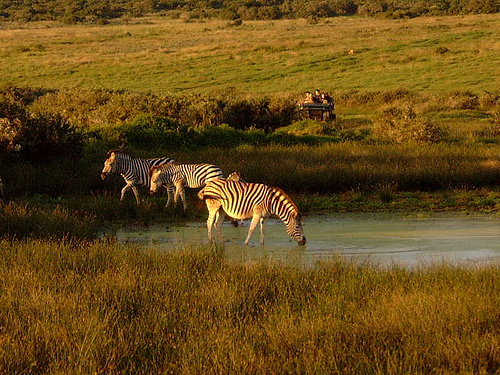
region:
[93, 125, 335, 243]
Zebra's in a pasture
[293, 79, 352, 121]
People watching the zebras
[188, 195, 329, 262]
Zebra drinking out of body of water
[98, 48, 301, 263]
Black and white stripes on zebras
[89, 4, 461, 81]
Brown and green grass in field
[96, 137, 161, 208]
Zebra walking in the grass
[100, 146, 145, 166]
Black hair on top of zebra's head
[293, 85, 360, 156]
People sitting watching zebras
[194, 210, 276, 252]
4 legs on zebra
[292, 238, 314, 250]
Black nose on zebra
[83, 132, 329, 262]
A group of zebras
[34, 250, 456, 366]
Tall yellow and green grass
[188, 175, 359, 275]
A zebra drink from water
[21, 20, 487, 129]
A hillside cover in grass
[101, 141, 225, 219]
A pair of zebras walking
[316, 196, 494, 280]
A small pond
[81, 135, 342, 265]
Zebras in their natural habitat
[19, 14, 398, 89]
Dead grass on the hill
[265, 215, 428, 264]
Ripples in water due to zebra drinking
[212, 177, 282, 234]
Stripes on a zebra's body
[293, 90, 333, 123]
a group of tourists on a safari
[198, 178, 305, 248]
a zebra drinking water from a watering hole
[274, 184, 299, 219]
a zebra has a brown mane along the back of its neck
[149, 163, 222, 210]
a zebra has vertical and horizontal black stripes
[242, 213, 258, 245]
the zebras front legs do not have any stripes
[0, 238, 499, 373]
tall grazing grass for the zebras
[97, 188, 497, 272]
a small watering hole in the plains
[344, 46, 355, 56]
a lion in the distance is watching the activity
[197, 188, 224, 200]
the zebra's tail has long black hairs at the tip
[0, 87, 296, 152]
thick vegetation surounds the watering hole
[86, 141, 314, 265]
Zebras in a creek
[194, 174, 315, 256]
Zebra drinking water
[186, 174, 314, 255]
Zebra has tail on right side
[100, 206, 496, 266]
Creek in the meadow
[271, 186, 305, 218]
Mane has brown borders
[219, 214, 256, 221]
Underbelly of zebra is white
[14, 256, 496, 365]
Grass is high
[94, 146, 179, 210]
Zebra walking in the bank of creek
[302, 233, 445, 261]
Ripples formed in the water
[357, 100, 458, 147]
Bush on the field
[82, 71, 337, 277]
zebras at pool of water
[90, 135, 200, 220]
two zebras headed the same way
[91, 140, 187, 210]
a pair of zebras walking together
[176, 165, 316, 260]
zebra drinking water from pond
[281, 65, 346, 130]
boxy structure above pond with objects on top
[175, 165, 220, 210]
tail curved around body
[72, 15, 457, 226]
sloped grassland above pond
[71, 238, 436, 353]
tall and thin vegetation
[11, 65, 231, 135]
bushes growing on edge of grassland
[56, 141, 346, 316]
curve at the end of the pond